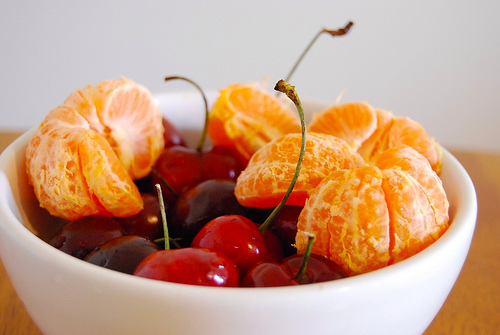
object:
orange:
[308, 102, 441, 176]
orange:
[235, 131, 366, 208]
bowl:
[0, 90, 479, 332]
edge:
[117, 273, 360, 308]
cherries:
[83, 236, 158, 277]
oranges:
[293, 144, 451, 276]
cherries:
[158, 146, 241, 196]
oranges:
[205, 83, 304, 157]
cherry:
[191, 79, 307, 270]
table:
[2, 126, 499, 332]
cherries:
[54, 216, 123, 257]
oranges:
[24, 77, 166, 222]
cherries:
[175, 179, 258, 228]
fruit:
[24, 75, 452, 287]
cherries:
[131, 248, 241, 290]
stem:
[256, 79, 308, 233]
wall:
[31, 0, 491, 142]